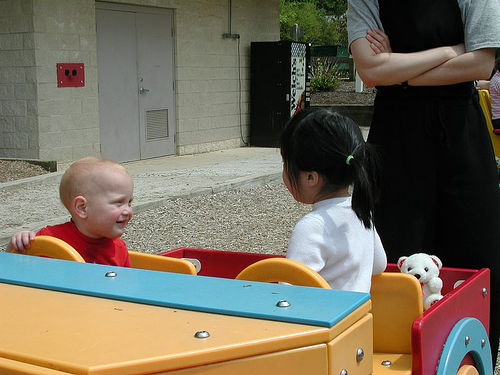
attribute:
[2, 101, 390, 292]
children — playing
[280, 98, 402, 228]
hair — black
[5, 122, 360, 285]
children — playing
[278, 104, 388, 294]
kids — playing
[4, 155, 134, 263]
kids — playing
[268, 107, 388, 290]
girl — toddler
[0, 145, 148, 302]
kid — playing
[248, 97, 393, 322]
kid — playing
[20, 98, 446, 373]
children — sitting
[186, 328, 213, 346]
button — silver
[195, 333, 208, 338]
bolt — silver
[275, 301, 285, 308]
bolt — silver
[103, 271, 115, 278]
bolt — silver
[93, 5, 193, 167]
door — metal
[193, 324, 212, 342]
button — silver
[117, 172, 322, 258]
gravel — is playground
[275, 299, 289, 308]
screws — metal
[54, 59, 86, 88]
plate — red, metal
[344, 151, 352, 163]
band — rubber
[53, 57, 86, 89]
sign — hazardous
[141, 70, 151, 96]
handle — chrome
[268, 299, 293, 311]
button — silver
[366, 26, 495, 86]
arms — crossed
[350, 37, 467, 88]
arms — crossed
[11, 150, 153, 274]
boy — baby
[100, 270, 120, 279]
button — silver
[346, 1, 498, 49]
shirt — grey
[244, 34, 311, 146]
machine — vending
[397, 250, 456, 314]
teddy bear — white, in back